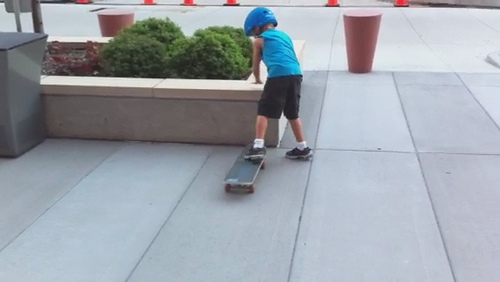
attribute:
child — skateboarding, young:
[243, 7, 312, 163]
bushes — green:
[100, 19, 252, 80]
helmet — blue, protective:
[244, 8, 280, 33]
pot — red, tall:
[341, 9, 380, 76]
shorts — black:
[256, 72, 303, 120]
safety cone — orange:
[326, 1, 339, 9]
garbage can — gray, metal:
[0, 32, 49, 156]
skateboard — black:
[222, 149, 266, 193]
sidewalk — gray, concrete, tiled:
[0, 1, 499, 72]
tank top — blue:
[255, 30, 301, 79]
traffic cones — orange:
[75, 1, 412, 7]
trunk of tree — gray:
[32, 0, 54, 64]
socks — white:
[253, 138, 310, 152]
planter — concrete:
[39, 34, 304, 149]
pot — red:
[97, 8, 135, 36]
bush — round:
[174, 34, 252, 80]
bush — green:
[98, 32, 169, 79]